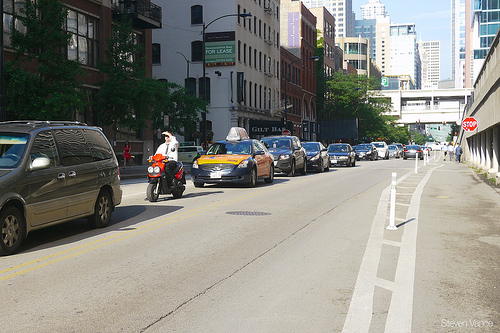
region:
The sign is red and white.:
[458, 109, 478, 135]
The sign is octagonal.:
[457, 113, 479, 137]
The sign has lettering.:
[459, 112, 480, 135]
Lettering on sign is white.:
[458, 113, 479, 133]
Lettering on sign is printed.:
[456, 113, 481, 134]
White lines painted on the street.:
[325, 136, 467, 331]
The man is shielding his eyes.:
[128, 115, 198, 217]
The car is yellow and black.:
[183, 123, 279, 201]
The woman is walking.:
[118, 130, 140, 173]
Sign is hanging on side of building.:
[133, 3, 245, 163]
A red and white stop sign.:
[459, 115, 476, 132]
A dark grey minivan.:
[2, 120, 123, 251]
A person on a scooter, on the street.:
[140, 129, 188, 206]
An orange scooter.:
[139, 152, 185, 202]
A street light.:
[197, 11, 254, 157]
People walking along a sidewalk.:
[414, 136, 498, 323]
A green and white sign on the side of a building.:
[204, 43, 236, 62]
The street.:
[7, 132, 439, 330]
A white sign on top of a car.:
[226, 126, 252, 142]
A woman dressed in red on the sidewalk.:
[114, 137, 139, 169]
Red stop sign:
[459, 111, 479, 135]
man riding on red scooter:
[142, 127, 190, 209]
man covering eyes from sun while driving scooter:
[144, 131, 191, 206]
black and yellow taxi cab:
[188, 122, 273, 195]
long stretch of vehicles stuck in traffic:
[3, 105, 428, 260]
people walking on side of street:
[428, 133, 470, 170]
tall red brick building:
[281, 3, 321, 140]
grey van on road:
[3, 111, 129, 256]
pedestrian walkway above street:
[346, 84, 474, 129]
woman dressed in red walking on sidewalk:
[118, 133, 136, 174]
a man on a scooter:
[136, 120, 199, 209]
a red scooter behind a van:
[137, 147, 191, 204]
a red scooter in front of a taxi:
[139, 143, 194, 205]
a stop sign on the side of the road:
[446, 111, 481, 136]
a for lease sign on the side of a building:
[190, 20, 244, 77]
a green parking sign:
[375, 71, 392, 87]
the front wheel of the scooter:
[142, 173, 160, 204]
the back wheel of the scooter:
[170, 171, 185, 196]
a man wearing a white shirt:
[150, 119, 191, 166]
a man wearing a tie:
[145, 127, 184, 167]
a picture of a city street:
[30, 24, 499, 196]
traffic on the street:
[23, 81, 402, 243]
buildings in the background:
[339, 5, 464, 160]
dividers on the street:
[366, 148, 448, 230]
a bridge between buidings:
[360, 75, 475, 131]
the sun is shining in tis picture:
[115, 10, 479, 287]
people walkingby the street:
[438, 133, 464, 167]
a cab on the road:
[198, 123, 280, 190]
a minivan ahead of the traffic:
[1, 112, 126, 255]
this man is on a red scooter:
[145, 127, 189, 200]